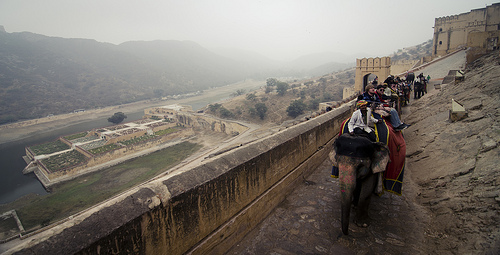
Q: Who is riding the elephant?
A: A man.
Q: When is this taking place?
A: Daytime.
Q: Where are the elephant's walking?
A: Walkway trail.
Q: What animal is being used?
A: Elephant.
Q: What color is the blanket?
A: Red.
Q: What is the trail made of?
A: Stone.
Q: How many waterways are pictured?
A: One.